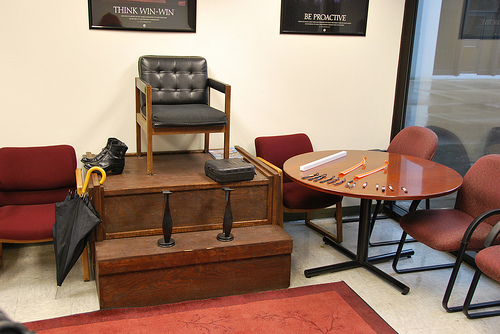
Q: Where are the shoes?
A: On the platform.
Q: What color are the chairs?
A: Red.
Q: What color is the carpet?
A: Red.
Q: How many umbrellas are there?
A: 1.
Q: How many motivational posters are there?
A: 2.